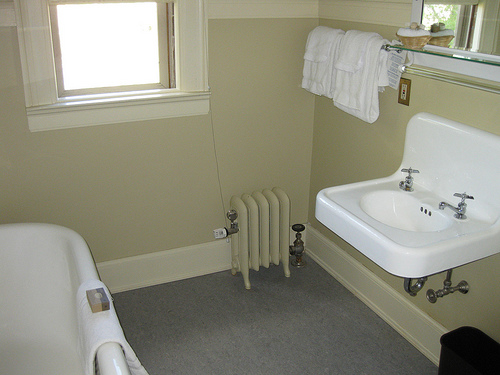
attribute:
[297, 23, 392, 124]
towel — white 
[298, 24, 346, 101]
towel — white, folded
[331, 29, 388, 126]
towel — folded, white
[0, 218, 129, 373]
bathtub — white , for bath, metal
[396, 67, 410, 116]
wallswitch —  for lights, of wall 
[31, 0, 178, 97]
window — small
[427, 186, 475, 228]
faucet — metal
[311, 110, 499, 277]
sink — white, tile, simple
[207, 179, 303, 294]
heater — small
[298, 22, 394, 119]
towels — white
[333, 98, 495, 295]
sink — white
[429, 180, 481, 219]
faucet — silver, shiny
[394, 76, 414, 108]
brown socket — small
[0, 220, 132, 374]
tub — white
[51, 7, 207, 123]
window — large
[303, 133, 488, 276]
sink — porcelain, white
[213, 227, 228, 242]
white screw — large